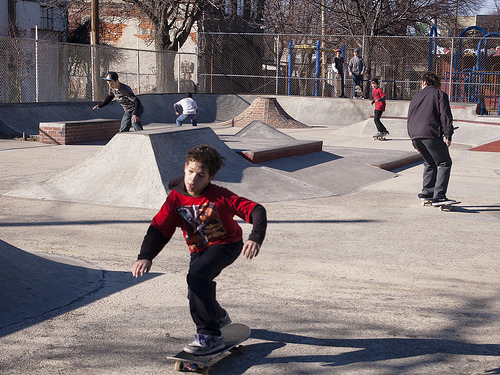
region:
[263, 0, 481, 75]
trees have no leaves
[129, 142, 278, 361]
young boy on skateboard in skate park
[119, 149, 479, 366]
boys shadow to his left on the ground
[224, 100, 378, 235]
cement ramps for the skateboarders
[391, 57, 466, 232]
adult playing on skateboard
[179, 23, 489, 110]
fence is behind the skateboard park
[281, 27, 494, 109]
behind the fence is a playground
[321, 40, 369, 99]
two boys are watching the skateboarders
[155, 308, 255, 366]
boy has one foot on skateboard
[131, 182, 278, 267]
boy wearing red shirt with cartoons on front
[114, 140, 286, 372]
a little boy is on a skateboard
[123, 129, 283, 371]
Boy wears red short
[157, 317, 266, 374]
skateboard is black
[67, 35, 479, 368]
several people are skating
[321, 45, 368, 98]
two boys are on side of skater field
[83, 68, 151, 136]
boy wears a black hat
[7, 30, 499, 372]
skate field if fenced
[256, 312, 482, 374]
shadow cast on field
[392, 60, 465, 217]
skater wears a long sleeve shirt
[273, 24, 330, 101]
two blue poles in the fence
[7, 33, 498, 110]
A grey chained length fence.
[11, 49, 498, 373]
A skatepark.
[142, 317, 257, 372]
A skateboard.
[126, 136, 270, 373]
A boy riding a skateboard.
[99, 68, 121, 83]
A dark colored ball cap.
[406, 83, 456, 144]
A dark colored hoodie.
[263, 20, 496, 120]
Playground equipment.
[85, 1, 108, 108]
A brown wooden street pole.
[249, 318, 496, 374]
A boy on a skateboards' shadow.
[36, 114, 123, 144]
A brick bench.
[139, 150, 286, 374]
small child skateboarding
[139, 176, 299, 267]
red short sleeved shirt of a male child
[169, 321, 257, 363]
gray and white skateboard shoes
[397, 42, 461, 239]
large adult with black hoodie skateboarding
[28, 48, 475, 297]
skate park with 5 skateboarders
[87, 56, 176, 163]
skateboarder on ramp with fitted ball cap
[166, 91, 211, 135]
skateboarder with white tee-shirt and blue jeans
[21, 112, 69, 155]
grind rail ast a skate park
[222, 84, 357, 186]
half pipe section at skate park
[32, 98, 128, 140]
grinding wall at skate park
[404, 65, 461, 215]
man wearing dark jacket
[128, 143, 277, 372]
boy on skateboard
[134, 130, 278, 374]
boy wearing long sleeved red shirt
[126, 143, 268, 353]
boy wearing black pants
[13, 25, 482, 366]
five males at skate park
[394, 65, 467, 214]
back of adult male on skateboard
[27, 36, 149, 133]
boy outside with chain link fence in background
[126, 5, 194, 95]
large tree trunk behind chain link fence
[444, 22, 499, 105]
blue playground equipment behind chain link fence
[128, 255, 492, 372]
shadow of boy on skateboard